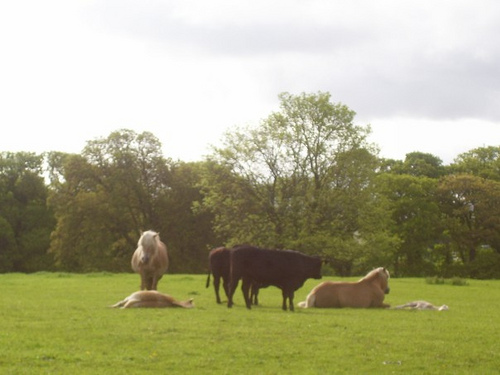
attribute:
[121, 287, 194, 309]
horse — laying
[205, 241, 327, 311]
cows — standing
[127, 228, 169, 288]
horse — standing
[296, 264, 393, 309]
horse — resting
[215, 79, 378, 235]
trees — tall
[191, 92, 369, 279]
tree — large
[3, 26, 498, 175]
sky — bright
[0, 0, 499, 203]
sky — grey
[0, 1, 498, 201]
clouds — white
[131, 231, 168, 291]
horse — standing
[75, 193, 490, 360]
grass — short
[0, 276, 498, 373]
field — lush, grassy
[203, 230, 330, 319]
cows — black